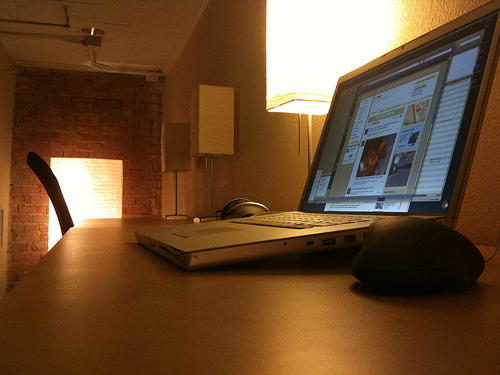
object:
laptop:
[132, 1, 499, 272]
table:
[0, 216, 499, 375]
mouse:
[349, 215, 487, 297]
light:
[261, 1, 395, 118]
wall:
[161, 1, 500, 248]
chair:
[27, 149, 77, 236]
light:
[189, 84, 236, 159]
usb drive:
[322, 238, 337, 246]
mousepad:
[170, 226, 244, 239]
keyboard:
[231, 212, 383, 230]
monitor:
[299, 7, 500, 214]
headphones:
[214, 197, 272, 221]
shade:
[159, 118, 192, 174]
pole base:
[307, 112, 314, 175]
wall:
[6, 69, 161, 290]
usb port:
[343, 234, 357, 243]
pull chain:
[297, 113, 301, 155]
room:
[1, 1, 500, 375]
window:
[48, 156, 124, 251]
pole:
[86, 42, 167, 78]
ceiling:
[2, 1, 173, 70]